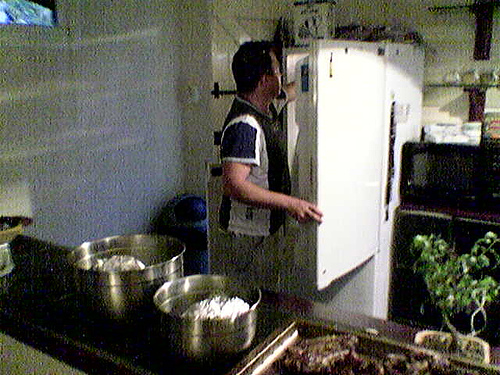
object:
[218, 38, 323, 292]
man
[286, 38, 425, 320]
refrigerator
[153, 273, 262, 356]
pot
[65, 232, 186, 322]
pot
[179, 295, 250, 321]
rice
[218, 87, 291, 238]
shirt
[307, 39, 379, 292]
refrigerator door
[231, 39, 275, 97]
hair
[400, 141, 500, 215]
microwave oven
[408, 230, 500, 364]
plant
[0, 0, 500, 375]
kitchen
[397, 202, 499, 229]
counter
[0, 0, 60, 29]
window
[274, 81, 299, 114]
arm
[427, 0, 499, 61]
shelf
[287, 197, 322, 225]
hand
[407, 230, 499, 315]
leaves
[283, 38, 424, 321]
fridge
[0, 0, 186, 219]
wall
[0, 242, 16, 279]
container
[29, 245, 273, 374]
stove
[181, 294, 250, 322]
noodles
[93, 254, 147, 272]
noodles